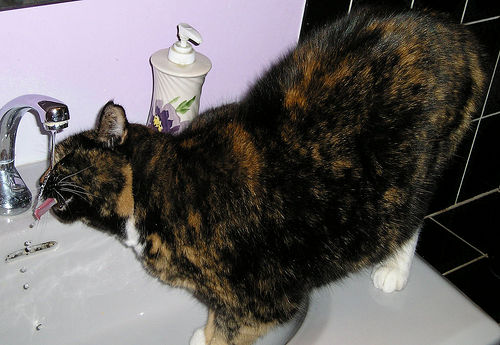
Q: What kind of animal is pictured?
A: Cat.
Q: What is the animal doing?
A: Drinking water.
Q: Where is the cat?
A: On the sink.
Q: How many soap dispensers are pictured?
A: One.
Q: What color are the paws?
A: White.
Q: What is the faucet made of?
A: Metal.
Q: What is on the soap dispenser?
A: Flowers.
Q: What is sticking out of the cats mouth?
A: It's tongue.